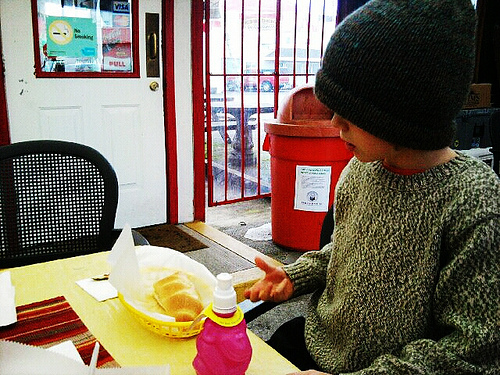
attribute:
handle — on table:
[144, 9, 159, 84]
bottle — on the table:
[174, 277, 291, 369]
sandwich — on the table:
[142, 261, 236, 338]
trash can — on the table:
[266, 85, 354, 248]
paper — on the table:
[101, 224, 216, 324]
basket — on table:
[86, 209, 253, 343]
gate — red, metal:
[198, 14, 268, 159]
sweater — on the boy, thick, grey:
[282, 153, 498, 372]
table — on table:
[40, 234, 344, 371]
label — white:
[282, 153, 339, 234]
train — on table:
[109, 240, 217, 343]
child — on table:
[254, 4, 497, 354]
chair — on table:
[4, 135, 130, 267]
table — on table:
[23, 237, 253, 373]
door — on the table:
[9, 0, 174, 215]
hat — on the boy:
[306, 3, 494, 161]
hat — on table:
[308, 1, 478, 159]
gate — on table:
[146, 13, 297, 200]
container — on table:
[181, 263, 262, 374]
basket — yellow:
[101, 229, 254, 355]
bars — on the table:
[207, 4, 334, 208]